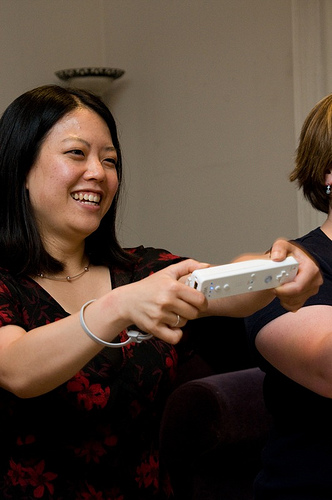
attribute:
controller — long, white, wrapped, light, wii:
[181, 254, 303, 298]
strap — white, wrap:
[78, 300, 160, 348]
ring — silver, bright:
[172, 313, 184, 327]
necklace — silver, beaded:
[31, 255, 93, 282]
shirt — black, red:
[0, 243, 196, 499]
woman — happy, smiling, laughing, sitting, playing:
[1, 83, 325, 498]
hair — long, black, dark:
[0, 86, 143, 270]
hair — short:
[291, 93, 330, 215]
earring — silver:
[324, 183, 331, 193]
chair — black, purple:
[157, 363, 270, 499]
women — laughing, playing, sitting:
[2, 84, 330, 498]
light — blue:
[208, 285, 216, 293]